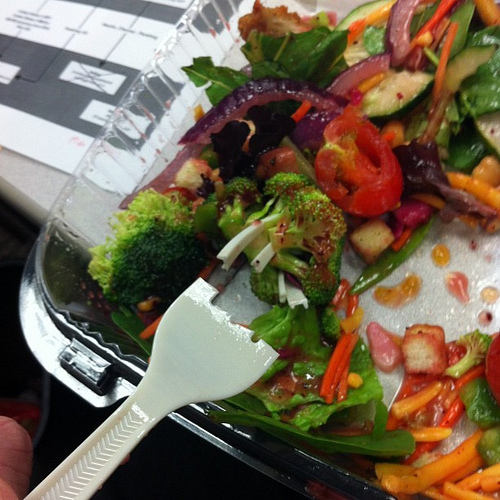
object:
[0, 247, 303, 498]
fork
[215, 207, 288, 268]
prong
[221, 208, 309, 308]
snapped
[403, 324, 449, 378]
crouton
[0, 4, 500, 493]
container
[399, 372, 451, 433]
cheese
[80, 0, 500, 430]
salad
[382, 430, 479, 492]
carrot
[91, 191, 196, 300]
broccoli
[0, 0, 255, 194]
paper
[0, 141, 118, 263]
table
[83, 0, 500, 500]
food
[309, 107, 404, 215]
tomato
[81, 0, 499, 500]
vegetables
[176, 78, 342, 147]
onion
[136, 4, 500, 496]
dressing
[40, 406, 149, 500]
chevron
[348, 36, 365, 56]
pepper